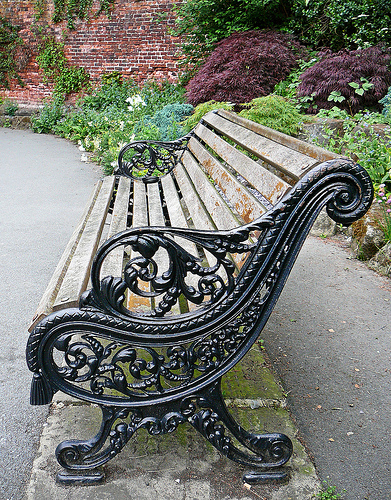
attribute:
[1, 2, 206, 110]
wall — red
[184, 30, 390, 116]
leaves — purple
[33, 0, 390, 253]
bushes — purple, green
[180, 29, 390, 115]
bushes — purple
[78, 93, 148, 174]
flowers — white